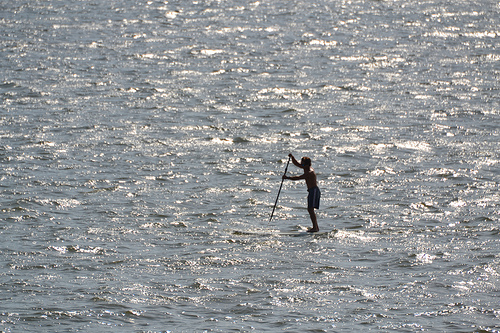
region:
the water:
[108, 171, 232, 282]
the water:
[187, 295, 228, 330]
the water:
[224, 305, 258, 330]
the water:
[171, 282, 253, 322]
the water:
[161, 257, 216, 322]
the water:
[211, 291, 251, 331]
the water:
[217, 267, 262, 308]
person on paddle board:
[254, 141, 326, 243]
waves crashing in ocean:
[76, 243, 113, 260]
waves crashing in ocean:
[341, 279, 381, 302]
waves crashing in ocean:
[326, 225, 384, 240]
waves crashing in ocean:
[199, 253, 244, 274]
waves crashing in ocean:
[203, 127, 239, 147]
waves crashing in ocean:
[389, 137, 428, 160]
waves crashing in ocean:
[281, 100, 303, 117]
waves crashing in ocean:
[221, 128, 248, 150]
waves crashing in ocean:
[189, 42, 222, 59]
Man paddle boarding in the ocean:
[257, 143, 372, 314]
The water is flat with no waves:
[53, 50, 130, 121]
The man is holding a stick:
[271, 147, 298, 225]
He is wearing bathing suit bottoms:
[305, 182, 334, 222]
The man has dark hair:
[300, 148, 312, 173]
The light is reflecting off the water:
[47, 167, 114, 219]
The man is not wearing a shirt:
[295, 137, 326, 197]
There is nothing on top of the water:
[25, 17, 317, 99]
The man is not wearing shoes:
[307, 205, 342, 249]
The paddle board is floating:
[293, 218, 338, 265]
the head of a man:
[296, 150, 317, 172]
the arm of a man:
[286, 169, 311, 187]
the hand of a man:
[278, 170, 290, 182]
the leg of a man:
[301, 187, 323, 233]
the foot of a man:
[303, 223, 322, 236]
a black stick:
[259, 148, 296, 223]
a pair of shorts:
[306, 181, 327, 211]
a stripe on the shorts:
[309, 187, 321, 207]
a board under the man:
[273, 214, 340, 244]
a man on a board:
[264, 136, 331, 238]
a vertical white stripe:
[310, 185, 320, 211]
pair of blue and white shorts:
[301, 184, 329, 213]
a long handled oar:
[266, 146, 293, 241]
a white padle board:
[233, 222, 343, 242]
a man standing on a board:
[238, 148, 380, 248]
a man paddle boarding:
[194, 144, 368, 252]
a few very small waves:
[86, 116, 253, 177]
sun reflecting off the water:
[401, 243, 444, 277]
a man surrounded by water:
[38, 96, 484, 321]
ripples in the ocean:
[10, 275, 46, 301]